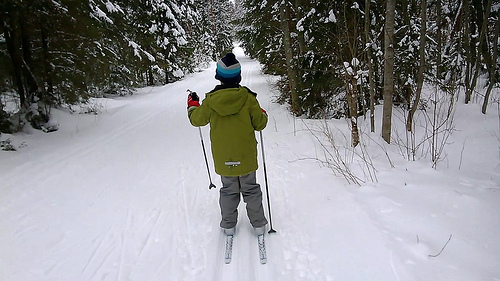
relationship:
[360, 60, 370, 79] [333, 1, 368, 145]
leaves on tree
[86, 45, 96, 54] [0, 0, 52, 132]
green leaves on tree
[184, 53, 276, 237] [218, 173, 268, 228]
boy wearing boy's pants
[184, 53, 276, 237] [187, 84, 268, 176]
boy wearing hoodie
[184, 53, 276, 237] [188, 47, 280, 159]
boy wearing hat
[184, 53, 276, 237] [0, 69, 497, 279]
boy on snow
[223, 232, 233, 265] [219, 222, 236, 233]
ski on foot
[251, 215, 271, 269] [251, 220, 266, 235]
ski on foot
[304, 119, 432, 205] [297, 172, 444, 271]
twigs in snow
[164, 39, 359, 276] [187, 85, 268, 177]
boy wearing hoodie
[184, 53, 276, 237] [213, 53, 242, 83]
boy wearing hat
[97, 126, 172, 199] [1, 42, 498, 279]
snow on ground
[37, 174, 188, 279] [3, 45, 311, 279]
snow on road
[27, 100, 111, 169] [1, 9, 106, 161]
snow on bushes